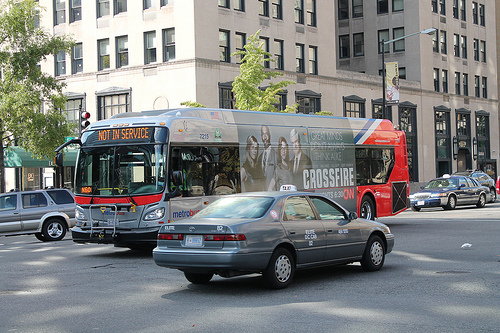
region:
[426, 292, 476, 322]
part of a road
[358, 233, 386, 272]
part of the front wheel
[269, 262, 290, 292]
part of a rear wheel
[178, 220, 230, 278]
back of a car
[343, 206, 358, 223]
part of a side mirror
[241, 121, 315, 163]
side of a bus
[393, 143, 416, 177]
edge of a bus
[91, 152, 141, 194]
part of a window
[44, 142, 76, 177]
part of a side mirror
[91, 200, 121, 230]
part of a guard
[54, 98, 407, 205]
A city bus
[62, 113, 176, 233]
A city bus that is not in service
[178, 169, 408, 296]
A grey taxi cab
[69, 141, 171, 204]
The windshield of a bus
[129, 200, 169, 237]
The headlight of a bus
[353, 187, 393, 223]
The tire of a bus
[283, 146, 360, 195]
White letters on a bus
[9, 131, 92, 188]
A green awning on a building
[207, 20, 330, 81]
Three windows in a building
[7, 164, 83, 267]
A grey SUV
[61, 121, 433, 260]
A COMMUTER BUS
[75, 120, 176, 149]
A NOT IN SERVICE SIGN ON A BUS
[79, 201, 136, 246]
A METAL BIKE RACK ON A BUS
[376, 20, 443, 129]
A TALL STREET LAMP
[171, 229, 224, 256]
A CARS LICENSE PLATE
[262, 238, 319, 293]
A CARS REAR TIRE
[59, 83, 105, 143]
A RED TRAFFIC LIGHT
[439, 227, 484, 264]
A PIECE OF TRASH ON THE STREET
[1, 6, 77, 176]
A TREE IN THE BACKGROUND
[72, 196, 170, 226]
A PAIR OF BUS HEADLIGHTS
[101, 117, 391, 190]
this is a bus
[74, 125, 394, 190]
the bus is long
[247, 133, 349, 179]
the bus is grey in color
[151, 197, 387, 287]
a taxi is beside the bus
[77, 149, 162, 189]
the rear screen is clear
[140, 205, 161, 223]
the rear light is off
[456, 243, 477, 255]
a paper is on the road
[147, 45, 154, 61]
the window is open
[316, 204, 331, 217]
the window is open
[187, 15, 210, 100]
the wall is white in color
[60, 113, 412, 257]
bus on city street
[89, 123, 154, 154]
orange words on front of bus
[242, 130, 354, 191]
advertisement on side of bus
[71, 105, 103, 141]
traffic light glowing red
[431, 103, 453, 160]
reflection on building windows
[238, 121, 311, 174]
four people in photo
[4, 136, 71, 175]
green awning over sidewalk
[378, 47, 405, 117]
vertical banner on pole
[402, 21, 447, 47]
street light on pole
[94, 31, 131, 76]
windows with open blinds